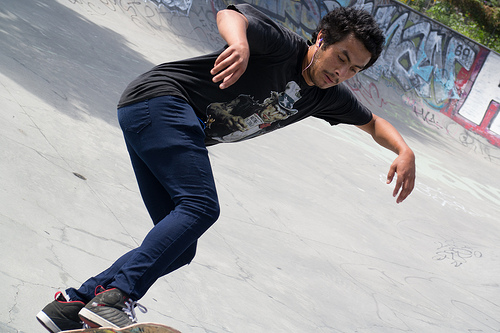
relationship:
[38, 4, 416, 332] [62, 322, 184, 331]
man on skateboard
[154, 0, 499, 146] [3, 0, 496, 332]
graffiti on pavement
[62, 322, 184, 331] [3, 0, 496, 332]
skateboard on pavement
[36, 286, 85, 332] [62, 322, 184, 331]
foot on skateboard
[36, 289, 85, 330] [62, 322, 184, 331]
foot on skateboard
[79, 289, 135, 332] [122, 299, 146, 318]
shoe has laces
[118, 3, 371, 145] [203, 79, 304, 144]
shirt has picture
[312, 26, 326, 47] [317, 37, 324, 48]
ear has earbud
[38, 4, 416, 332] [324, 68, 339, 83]
man has mustache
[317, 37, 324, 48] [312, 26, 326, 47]
earbud in ear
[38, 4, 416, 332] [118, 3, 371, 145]
man wearing shirt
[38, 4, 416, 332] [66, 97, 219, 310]
man wearing jeans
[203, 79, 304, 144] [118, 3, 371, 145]
picture on shirt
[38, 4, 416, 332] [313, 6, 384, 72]
man has hair